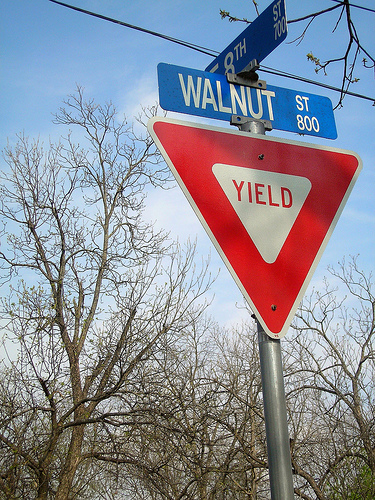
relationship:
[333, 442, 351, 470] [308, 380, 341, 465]
leave in corner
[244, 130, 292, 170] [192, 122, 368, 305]
bolt on sig